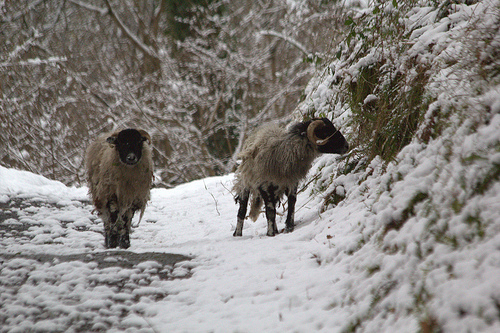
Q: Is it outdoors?
A: Yes, it is outdoors.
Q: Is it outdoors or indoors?
A: It is outdoors.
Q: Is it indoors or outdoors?
A: It is outdoors.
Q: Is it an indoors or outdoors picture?
A: It is outdoors.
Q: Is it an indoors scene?
A: No, it is outdoors.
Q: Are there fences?
A: No, there are no fences.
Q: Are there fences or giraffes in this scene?
A: No, there are no fences or giraffes.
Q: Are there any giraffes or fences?
A: No, there are no fences or giraffes.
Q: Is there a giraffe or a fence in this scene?
A: No, there are no fences or giraffes.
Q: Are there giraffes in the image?
A: No, there are no giraffes.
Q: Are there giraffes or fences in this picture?
A: No, there are no giraffes or fences.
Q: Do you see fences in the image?
A: No, there are no fences.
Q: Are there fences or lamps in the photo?
A: No, there are no fences or lamps.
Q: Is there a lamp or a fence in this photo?
A: No, there are no fences or lamps.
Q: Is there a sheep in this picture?
A: Yes, there is a sheep.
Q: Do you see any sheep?
A: Yes, there is a sheep.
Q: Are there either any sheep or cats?
A: Yes, there is a sheep.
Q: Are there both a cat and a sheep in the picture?
A: No, there is a sheep but no cats.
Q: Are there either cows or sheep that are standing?
A: Yes, the sheep is standing.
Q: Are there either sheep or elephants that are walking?
A: Yes, the sheep is walking.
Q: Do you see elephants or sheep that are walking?
A: Yes, the sheep is walking.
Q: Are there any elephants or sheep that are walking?
A: Yes, the sheep is walking.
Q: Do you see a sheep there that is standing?
A: Yes, there is a sheep that is standing.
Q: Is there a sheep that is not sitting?
A: Yes, there is a sheep that is standing.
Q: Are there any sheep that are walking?
A: Yes, there is a sheep that is walking.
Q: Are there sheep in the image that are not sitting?
A: Yes, there is a sheep that is walking.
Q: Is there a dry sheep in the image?
A: Yes, there is a dry sheep.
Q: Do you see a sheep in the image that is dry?
A: Yes, there is a sheep that is dry.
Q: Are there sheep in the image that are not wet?
A: Yes, there is a dry sheep.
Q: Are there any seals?
A: No, there are no seals.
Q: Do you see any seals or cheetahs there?
A: No, there are no seals or cheetahs.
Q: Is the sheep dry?
A: Yes, the sheep is dry.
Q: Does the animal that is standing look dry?
A: Yes, the sheep is dry.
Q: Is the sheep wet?
A: No, the sheep is dry.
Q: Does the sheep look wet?
A: No, the sheep is dry.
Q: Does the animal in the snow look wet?
A: No, the sheep is dry.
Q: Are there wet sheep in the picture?
A: No, there is a sheep but it is dry.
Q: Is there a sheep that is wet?
A: No, there is a sheep but it is dry.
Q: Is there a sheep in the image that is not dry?
A: No, there is a sheep but it is dry.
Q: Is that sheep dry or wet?
A: The sheep is dry.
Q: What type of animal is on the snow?
A: The animal is a sheep.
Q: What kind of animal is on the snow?
A: The animal is a sheep.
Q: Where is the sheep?
A: The sheep is on the snow.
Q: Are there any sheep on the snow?
A: Yes, there is a sheep on the snow.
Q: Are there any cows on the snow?
A: No, there is a sheep on the snow.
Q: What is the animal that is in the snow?
A: The animal is a sheep.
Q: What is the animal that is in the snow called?
A: The animal is a sheep.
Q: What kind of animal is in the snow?
A: The animal is a sheep.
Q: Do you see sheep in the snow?
A: Yes, there is a sheep in the snow.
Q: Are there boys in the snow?
A: No, there is a sheep in the snow.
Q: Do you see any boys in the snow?
A: No, there is a sheep in the snow.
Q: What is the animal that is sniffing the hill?
A: The animal is a sheep.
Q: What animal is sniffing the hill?
A: The animal is a sheep.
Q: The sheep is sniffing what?
A: The sheep is sniffing the hill.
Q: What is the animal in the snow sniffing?
A: The sheep is sniffing the hill.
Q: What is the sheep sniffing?
A: The sheep is sniffing the hill.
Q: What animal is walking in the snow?
A: The sheep is walking in the snow.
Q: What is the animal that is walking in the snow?
A: The animal is a sheep.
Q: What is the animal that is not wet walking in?
A: The sheep is walking in the snow.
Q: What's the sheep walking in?
A: The sheep is walking in the snow.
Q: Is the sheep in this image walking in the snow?
A: Yes, the sheep is walking in the snow.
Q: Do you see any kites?
A: No, there are no kites.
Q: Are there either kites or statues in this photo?
A: No, there are no kites or statues.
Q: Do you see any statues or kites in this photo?
A: No, there are no kites or statues.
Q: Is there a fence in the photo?
A: No, there are no fences.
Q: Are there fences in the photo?
A: No, there are no fences.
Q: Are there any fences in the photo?
A: No, there are no fences.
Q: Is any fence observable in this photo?
A: No, there are no fences.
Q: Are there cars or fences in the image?
A: No, there are no fences or cars.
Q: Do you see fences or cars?
A: No, there are no fences or cars.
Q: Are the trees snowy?
A: Yes, the trees are snowy.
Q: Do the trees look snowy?
A: Yes, the trees are snowy.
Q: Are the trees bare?
A: No, the trees are snowy.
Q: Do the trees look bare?
A: No, the trees are snowy.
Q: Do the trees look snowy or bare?
A: The trees are snowy.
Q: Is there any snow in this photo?
A: Yes, there is snow.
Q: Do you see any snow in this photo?
A: Yes, there is snow.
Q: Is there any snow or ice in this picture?
A: Yes, there is snow.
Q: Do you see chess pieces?
A: No, there are no chess pieces.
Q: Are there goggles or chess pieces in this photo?
A: No, there are no chess pieces or goggles.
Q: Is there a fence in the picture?
A: No, there are no fences.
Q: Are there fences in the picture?
A: No, there are no fences.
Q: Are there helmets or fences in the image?
A: No, there are no fences or helmets.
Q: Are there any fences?
A: No, there are no fences.